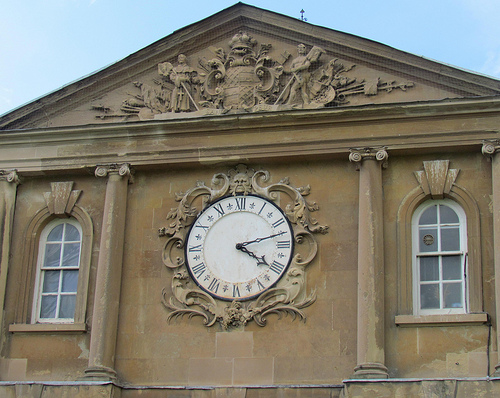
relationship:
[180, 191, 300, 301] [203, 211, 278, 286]
clock has face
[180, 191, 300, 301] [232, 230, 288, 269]
clock has hands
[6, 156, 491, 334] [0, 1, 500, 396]
window on building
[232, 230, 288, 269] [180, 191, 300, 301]
hands are on clock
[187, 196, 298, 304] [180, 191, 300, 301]
numbers on clock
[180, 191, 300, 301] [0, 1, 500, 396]
clock on building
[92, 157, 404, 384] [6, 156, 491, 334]
columns next to window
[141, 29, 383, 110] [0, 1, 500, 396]
sculpture on building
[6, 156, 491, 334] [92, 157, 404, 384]
window next to columns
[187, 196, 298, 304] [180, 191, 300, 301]
numbers are on clock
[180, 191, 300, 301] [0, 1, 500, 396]
clock on front of building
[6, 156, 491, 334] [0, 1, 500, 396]
window on front of building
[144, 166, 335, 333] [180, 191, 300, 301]
art surrounding clock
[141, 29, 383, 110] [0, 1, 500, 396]
sculpture on top of building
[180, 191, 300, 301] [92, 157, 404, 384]
clock between columns